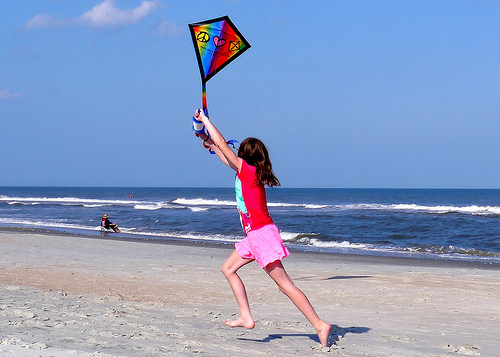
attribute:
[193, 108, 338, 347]
girl — running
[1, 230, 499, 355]
beach — sandy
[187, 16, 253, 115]
kite — rainbow, colorful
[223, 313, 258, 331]
foot — in the air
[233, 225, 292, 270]
shorts — pink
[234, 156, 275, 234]
shirt — red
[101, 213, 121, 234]
person — sitting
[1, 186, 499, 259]
water — calm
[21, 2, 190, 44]
clouds — white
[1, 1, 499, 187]
sky — blue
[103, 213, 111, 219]
hat — brown